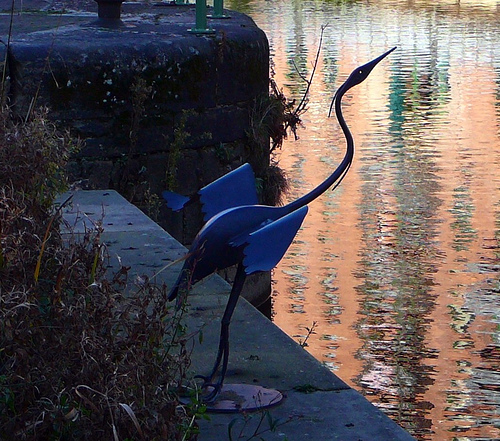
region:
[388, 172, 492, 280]
the water is clear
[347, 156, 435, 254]
the water is clear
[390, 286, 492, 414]
the water is clear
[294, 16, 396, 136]
the water is clear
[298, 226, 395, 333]
the water is clear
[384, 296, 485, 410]
the water is clear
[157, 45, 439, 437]
fake bird on the shore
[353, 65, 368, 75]
small hole in the head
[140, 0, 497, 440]
small body of water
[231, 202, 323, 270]
wing on the side of the bird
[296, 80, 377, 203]
long and thin neck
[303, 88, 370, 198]
neck is curved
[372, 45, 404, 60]
long and narrow beak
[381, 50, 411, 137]
reflection in the water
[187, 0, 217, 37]
bottom of a green pole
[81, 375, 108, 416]
part of a plant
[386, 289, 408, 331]
part of a shade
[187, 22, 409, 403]
this is a bird statue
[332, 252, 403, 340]
the water is clear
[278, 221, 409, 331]
the water is clear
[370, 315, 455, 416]
the water is clear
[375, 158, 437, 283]
the water is clear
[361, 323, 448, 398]
the water is clear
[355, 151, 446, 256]
the water is clear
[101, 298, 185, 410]
this is long grass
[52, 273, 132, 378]
this is long grass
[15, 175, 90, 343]
this is long grass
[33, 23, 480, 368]
this is a sculpture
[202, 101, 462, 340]
the sculpture is of a bird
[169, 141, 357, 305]
the bird is blue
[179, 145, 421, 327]
the bird is a heron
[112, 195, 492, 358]
this is a waterfront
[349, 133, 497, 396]
the water reflections are pink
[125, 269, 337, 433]
the ledge is concrete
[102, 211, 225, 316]
the ledge is green and blue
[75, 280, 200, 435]
this is tall grass brush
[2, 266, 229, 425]
the brush is green and brown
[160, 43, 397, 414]
blue metal statue of a bird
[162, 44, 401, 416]
blue metal statue on a round base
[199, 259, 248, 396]
metal legs of a blue heron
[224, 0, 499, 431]
pink and silver reflections in the rippled water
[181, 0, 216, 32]
green post on a square base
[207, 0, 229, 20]
green post on a square base